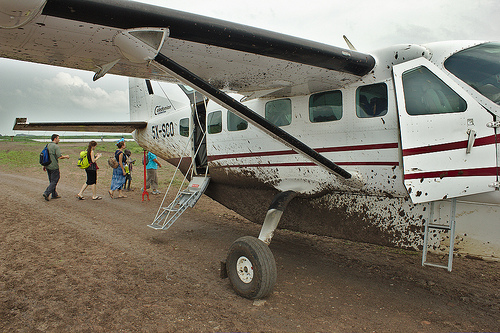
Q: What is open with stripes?
A: Cockpit door.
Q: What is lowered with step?
A: Airplane door.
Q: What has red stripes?
A: Airplane.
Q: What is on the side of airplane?
A: Mud.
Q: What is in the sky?
A: Clouds.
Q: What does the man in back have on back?
A: Back pack.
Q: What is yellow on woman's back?
A: Back pack.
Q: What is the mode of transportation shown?
A: Airplane.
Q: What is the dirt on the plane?
A: Mud.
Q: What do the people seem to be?
A: Tourists.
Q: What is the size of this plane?
A: Small.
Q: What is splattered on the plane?
A: Mud.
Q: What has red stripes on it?
A: Plane.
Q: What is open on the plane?
A: Doors.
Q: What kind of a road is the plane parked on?
A: Dirt.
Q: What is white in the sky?
A: Clouds.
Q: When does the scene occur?
A: Daytime.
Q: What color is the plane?
A: White.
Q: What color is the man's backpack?
A: Blue.